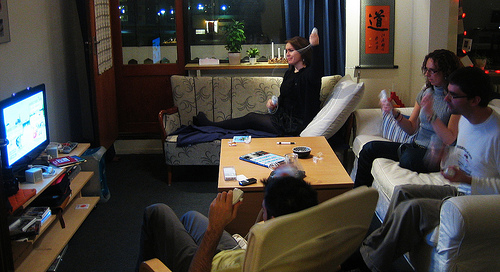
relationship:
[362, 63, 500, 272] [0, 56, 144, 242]
man playing wii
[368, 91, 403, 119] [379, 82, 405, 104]
hand holding remote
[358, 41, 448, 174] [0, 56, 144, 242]
woman playing wii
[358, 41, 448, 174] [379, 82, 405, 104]
woman holding remote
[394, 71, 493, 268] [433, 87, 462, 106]
man wearing glasses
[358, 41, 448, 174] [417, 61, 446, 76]
woman wearing glasses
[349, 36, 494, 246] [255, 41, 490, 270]
two people on couch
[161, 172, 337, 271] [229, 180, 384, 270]
guy in chair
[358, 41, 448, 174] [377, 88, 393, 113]
woman holding remote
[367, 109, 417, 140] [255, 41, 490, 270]
pillow on couch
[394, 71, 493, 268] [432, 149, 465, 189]
man holding controller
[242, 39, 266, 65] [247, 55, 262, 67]
plant in pot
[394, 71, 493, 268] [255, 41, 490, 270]
people on couch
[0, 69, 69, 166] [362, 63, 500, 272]
tv facing man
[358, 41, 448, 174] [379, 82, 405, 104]
person with remote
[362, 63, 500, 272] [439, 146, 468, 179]
man with controller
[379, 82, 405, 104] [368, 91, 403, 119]
remote in hand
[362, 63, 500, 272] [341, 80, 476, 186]
man playing game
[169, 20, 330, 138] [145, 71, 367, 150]
girl on sofa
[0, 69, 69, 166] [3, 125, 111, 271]
tv on console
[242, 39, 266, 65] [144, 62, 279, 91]
plant on counter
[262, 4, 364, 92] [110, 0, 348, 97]
curtain on window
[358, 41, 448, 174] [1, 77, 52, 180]
girl playing game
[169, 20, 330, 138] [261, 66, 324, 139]
girl in sweater